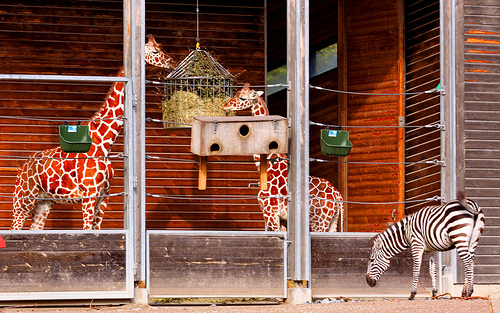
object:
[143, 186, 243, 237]
shadow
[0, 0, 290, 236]
wall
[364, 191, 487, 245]
zebra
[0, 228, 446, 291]
divider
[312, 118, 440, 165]
feeder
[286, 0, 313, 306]
post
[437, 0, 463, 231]
post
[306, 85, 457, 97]
cable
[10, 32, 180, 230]
giraffe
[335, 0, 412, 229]
wall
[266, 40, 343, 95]
windows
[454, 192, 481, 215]
tail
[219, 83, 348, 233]
giraffe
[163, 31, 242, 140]
feeder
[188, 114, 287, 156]
holed box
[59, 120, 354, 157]
containers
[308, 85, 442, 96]
cable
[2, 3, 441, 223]
cage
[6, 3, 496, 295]
enclosure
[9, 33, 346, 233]
giraffes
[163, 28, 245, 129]
wire basket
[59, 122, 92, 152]
container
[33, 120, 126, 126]
wire